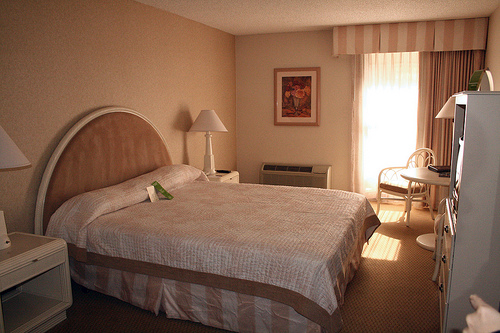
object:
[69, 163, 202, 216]
large pillow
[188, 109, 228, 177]
lamp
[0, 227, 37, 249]
table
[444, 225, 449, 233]
handle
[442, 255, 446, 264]
handle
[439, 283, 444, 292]
handle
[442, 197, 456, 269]
drawer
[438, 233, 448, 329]
drawer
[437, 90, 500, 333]
cupboard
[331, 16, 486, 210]
curtain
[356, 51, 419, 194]
window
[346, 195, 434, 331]
floor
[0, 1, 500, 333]
bedroom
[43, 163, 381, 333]
blanket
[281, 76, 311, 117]
ruffle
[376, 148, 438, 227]
chair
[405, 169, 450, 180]
table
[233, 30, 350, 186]
wall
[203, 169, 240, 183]
end table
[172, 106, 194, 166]
shadow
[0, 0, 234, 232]
wall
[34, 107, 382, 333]
bed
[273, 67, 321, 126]
painting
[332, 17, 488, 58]
valance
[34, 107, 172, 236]
headboard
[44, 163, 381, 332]
dust ruffle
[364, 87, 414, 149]
sun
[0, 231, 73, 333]
chest